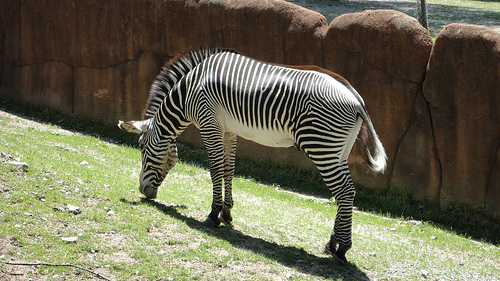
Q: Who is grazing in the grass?
A: A zebra.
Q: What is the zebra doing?
A: Grazing.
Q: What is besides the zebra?
A: Stone wall.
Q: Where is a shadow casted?
A: Under zebra.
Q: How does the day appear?
A: Sunny.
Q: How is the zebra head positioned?
A: Downwards.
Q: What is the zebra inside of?
A: An enclosure.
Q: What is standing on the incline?
A: A zebra.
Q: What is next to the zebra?
A: A stone wall.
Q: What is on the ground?
A: Grass.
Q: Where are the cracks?
A: In the wall.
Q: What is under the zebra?
A: A shadow.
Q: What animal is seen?
A: Zebra.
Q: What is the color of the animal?
A: Black and white.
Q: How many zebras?
A: One.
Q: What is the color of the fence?
A: Brown.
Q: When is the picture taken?
A: Daytime.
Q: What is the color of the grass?
A: Green.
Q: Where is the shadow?
A: In the ground.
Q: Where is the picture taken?
A: At the zoo.